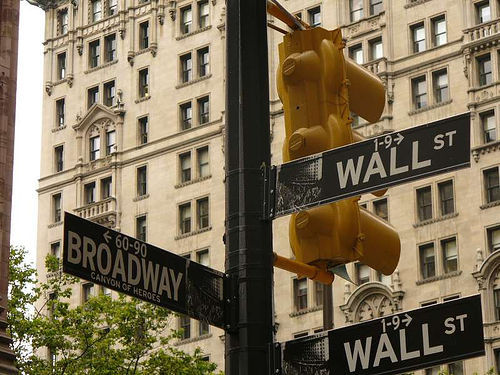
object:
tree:
[6, 242, 223, 373]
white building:
[71, 40, 250, 230]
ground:
[408, 141, 434, 172]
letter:
[336, 154, 364, 189]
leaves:
[40, 290, 162, 345]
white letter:
[370, 330, 398, 368]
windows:
[179, 97, 193, 131]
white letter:
[362, 151, 387, 181]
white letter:
[81, 235, 96, 271]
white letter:
[389, 146, 408, 176]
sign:
[63, 208, 228, 329]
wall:
[88, 54, 260, 212]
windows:
[196, 43, 212, 78]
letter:
[97, 241, 112, 276]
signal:
[275, 26, 400, 284]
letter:
[168, 268, 183, 301]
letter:
[139, 258, 159, 291]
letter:
[126, 252, 142, 286]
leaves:
[105, 338, 180, 367]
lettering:
[64, 233, 83, 263]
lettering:
[411, 140, 432, 171]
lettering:
[421, 323, 444, 356]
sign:
[273, 292, 484, 375]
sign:
[270, 109, 471, 220]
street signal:
[263, 0, 408, 287]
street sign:
[270, 292, 486, 375]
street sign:
[264, 104, 474, 213]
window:
[436, 66, 449, 100]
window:
[410, 71, 430, 105]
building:
[35, 0, 500, 375]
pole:
[226, 2, 270, 375]